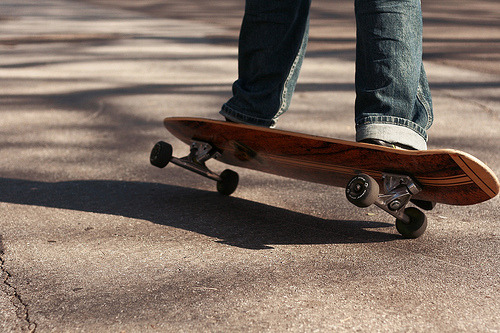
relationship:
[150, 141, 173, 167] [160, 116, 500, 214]
wheel on skateboard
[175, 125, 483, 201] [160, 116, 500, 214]
back of skateboard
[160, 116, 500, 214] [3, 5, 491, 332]
skateboard on top of street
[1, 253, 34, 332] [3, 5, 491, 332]
crack in street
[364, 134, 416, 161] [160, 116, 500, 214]
feet on top of skateboard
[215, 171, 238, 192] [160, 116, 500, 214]
wheel on skateboard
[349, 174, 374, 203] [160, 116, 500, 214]
wheel on skateboard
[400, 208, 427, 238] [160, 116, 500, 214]
wheel on skateboard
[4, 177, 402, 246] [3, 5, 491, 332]
shadow on street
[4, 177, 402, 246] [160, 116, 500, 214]
shadow of skateboard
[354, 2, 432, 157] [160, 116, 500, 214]
leg on top of skateboard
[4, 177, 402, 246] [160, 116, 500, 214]
shadow under skateboard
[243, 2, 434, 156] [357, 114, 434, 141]
jeans has seams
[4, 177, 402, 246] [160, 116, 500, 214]
shadow behind skateboard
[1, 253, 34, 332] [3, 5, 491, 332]
crack on street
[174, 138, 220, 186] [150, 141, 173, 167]
axle in between wheel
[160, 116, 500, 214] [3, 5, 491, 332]
skateboard on street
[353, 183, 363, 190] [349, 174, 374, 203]
bolt attaching wheel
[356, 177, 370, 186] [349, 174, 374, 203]
writing on wheel